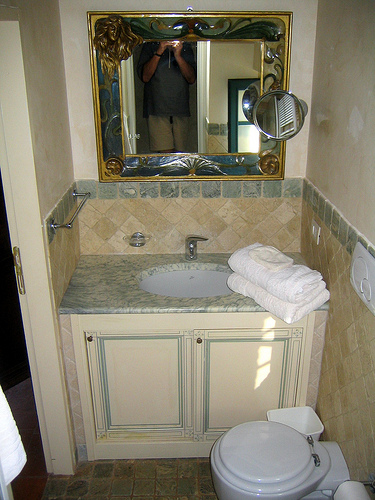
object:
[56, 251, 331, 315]
countertop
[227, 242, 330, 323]
towels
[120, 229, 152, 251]
soap dish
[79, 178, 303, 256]
wall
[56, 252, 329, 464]
counter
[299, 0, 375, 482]
wall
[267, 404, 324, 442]
trash can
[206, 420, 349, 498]
toilet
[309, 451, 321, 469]
toilet hinges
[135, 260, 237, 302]
sink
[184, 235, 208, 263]
faucet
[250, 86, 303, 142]
mirror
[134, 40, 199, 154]
man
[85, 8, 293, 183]
mirror border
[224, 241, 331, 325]
towel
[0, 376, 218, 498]
floor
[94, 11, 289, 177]
mirror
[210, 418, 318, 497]
cover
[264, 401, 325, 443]
gabag can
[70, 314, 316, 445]
drawers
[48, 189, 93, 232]
towel holder